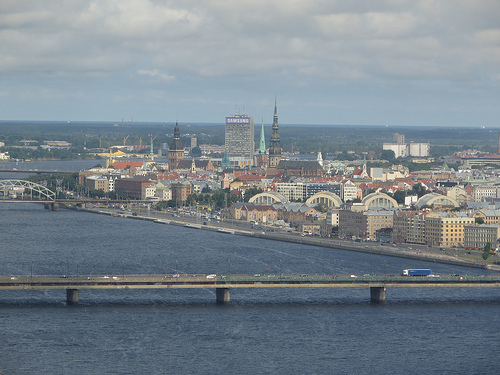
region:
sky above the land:
[170, 16, 320, 91]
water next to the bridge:
[164, 323, 230, 371]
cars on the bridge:
[167, 251, 258, 299]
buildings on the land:
[293, 156, 383, 221]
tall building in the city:
[253, 88, 309, 159]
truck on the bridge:
[386, 252, 434, 292]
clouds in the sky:
[131, 35, 208, 82]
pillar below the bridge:
[208, 286, 240, 310]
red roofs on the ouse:
[353, 171, 401, 203]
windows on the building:
[415, 216, 460, 248]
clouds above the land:
[145, 20, 311, 110]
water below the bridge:
[250, 315, 311, 370]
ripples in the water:
[260, 322, 320, 362]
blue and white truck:
[386, 255, 436, 287]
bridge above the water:
[70, 242, 411, 338]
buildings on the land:
[300, 151, 425, 251]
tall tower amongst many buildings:
[245, 71, 310, 156]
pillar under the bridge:
[200, 280, 250, 315]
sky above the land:
[142, 15, 257, 85]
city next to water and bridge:
[122, 117, 475, 329]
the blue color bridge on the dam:
[384, 258, 438, 284]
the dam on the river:
[109, 253, 269, 334]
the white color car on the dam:
[191, 263, 236, 283]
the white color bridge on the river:
[7, 175, 75, 225]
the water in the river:
[268, 322, 353, 362]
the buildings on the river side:
[297, 178, 434, 259]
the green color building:
[254, 120, 274, 167]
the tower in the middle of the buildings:
[261, 96, 289, 165]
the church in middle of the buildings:
[184, 155, 206, 180]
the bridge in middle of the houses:
[295, 180, 354, 227]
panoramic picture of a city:
[27, 95, 460, 297]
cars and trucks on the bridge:
[19, 255, 491, 311]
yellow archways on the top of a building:
[237, 182, 457, 221]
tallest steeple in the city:
[259, 90, 287, 161]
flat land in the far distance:
[41, 102, 475, 154]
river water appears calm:
[124, 313, 435, 353]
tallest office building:
[218, 108, 258, 163]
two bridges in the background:
[8, 156, 98, 223]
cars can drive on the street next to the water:
[117, 200, 411, 250]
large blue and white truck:
[393, 261, 441, 278]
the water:
[181, 336, 232, 365]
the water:
[287, 342, 339, 359]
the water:
[311, 345, 317, 350]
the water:
[280, 359, 339, 373]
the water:
[283, 316, 373, 352]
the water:
[147, 226, 365, 325]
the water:
[191, 288, 317, 334]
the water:
[257, 334, 262, 339]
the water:
[242, 316, 364, 371]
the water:
[244, 297, 342, 352]